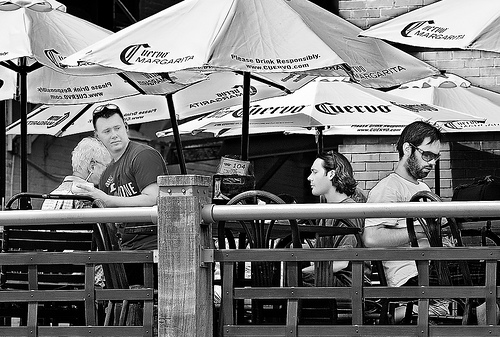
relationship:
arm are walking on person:
[82, 180, 158, 206] [60, 99, 175, 205]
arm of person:
[366, 225, 426, 247] [366, 120, 495, 288]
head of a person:
[90, 103, 134, 152] [79, 101, 184, 323]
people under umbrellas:
[58, 107, 463, 296] [1, 4, 498, 131]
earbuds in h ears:
[85, 118, 130, 171] [86, 122, 101, 139]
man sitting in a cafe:
[360, 120, 465, 290] [0, 3, 498, 335]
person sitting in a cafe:
[305, 144, 369, 291] [0, 3, 498, 335]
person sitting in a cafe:
[72, 107, 177, 222] [0, 3, 498, 335]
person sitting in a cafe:
[40, 134, 122, 209] [0, 3, 498, 335]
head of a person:
[296, 144, 356, 196] [306, 159, 363, 197]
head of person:
[72, 135, 110, 195] [42, 135, 105, 209]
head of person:
[90, 96, 135, 149] [96, 101, 162, 206]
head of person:
[306, 153, 356, 197] [303, 153, 361, 288]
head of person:
[399, 121, 443, 180] [361, 120, 445, 288]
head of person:
[388, 117, 452, 191] [362, 117, 478, 328]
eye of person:
[420, 149, 430, 161] [369, 120, 498, 305]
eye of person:
[311, 164, 321, 176] [304, 149, 363, 283]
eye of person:
[112, 124, 119, 131] [93, 103, 166, 324]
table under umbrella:
[212, 205, 364, 245] [55, 0, 445, 160]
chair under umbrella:
[212, 185, 303, 321] [55, 0, 445, 160]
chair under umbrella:
[297, 215, 367, 320] [55, 0, 445, 160]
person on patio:
[72, 107, 177, 222] [0, 168, 495, 335]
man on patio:
[360, 120, 465, 290] [0, 168, 495, 335]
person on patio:
[295, 134, 370, 291] [0, 168, 495, 335]